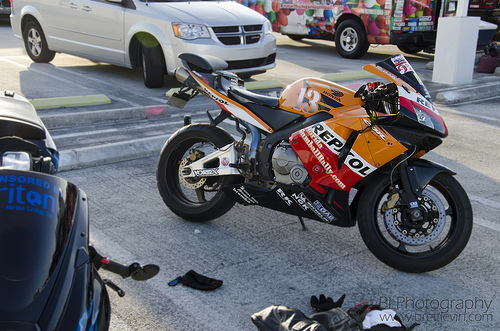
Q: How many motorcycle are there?
A: Two.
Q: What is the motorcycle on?
A: Street.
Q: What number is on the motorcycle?
A: 13.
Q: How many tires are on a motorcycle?
A: 2.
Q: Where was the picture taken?
A: Outside on the street.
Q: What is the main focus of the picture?
A: The motorcycle.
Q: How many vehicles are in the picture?
A: 4.